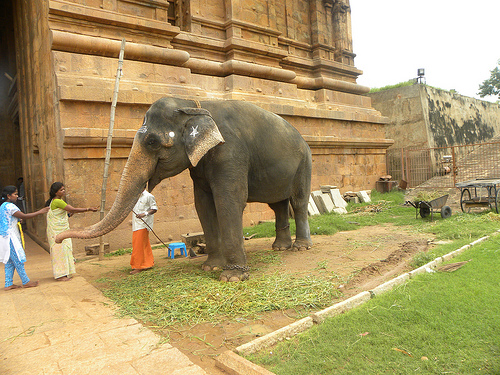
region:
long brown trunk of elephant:
[53, 153, 147, 239]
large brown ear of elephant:
[179, 108, 226, 169]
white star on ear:
[188, 124, 198, 144]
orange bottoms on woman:
[122, 228, 155, 273]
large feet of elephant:
[192, 250, 263, 301]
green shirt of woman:
[38, 198, 75, 231]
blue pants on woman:
[4, 254, 36, 296]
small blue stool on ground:
[158, 234, 189, 269]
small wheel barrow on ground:
[412, 191, 457, 224]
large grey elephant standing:
[47, 73, 354, 290]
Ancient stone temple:
[19, 3, 409, 251]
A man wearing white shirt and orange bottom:
[118, 180, 158, 273]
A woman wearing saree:
[41, 174, 83, 286]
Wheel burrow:
[404, 192, 459, 221]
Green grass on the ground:
[408, 266, 485, 373]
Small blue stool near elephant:
[163, 240, 191, 262]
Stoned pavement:
[3, 286, 166, 373]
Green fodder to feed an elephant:
[103, 264, 348, 331]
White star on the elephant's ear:
[177, 105, 222, 170]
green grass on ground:
[263, 349, 285, 369]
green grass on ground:
[316, 342, 342, 360]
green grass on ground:
[355, 308, 381, 333]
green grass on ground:
[393, 296, 421, 318]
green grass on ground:
[421, 318, 461, 358]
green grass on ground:
[201, 290, 235, 315]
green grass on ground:
[165, 288, 192, 318]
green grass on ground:
[144, 278, 184, 331]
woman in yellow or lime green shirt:
[38, 182, 105, 285]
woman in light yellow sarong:
[42, 178, 102, 288]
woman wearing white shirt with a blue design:
[0, 182, 52, 299]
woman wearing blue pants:
[0, 180, 52, 301]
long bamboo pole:
[90, 34, 132, 269]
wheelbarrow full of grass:
[400, 182, 455, 225]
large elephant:
[51, 93, 321, 286]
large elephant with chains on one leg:
[47, 92, 317, 288]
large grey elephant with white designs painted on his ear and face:
[49, 91, 317, 286]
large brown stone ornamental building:
[0, 5, 397, 266]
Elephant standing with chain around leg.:
[48, 83, 317, 284]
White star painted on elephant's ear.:
[183, 119, 206, 141]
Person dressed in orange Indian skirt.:
[120, 225, 162, 273]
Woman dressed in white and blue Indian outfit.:
[0, 200, 32, 295]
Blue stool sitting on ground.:
[160, 237, 193, 260]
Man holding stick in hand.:
[128, 203, 170, 253]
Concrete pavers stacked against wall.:
[310, 181, 356, 216]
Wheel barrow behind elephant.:
[396, 186, 456, 226]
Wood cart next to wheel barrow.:
[456, 172, 499, 217]